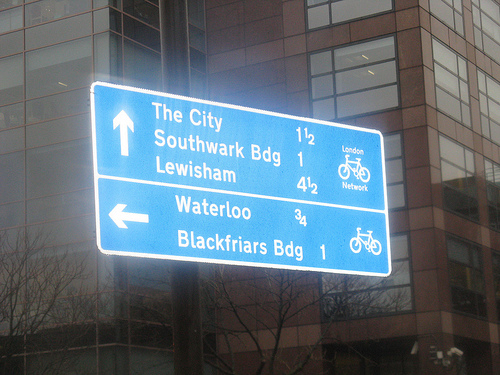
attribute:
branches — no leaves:
[182, 269, 387, 373]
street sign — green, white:
[87, 77, 394, 281]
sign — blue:
[87, 80, 395, 279]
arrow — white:
[108, 110, 134, 159]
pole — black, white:
[169, 280, 209, 372]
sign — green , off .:
[52, 62, 403, 295]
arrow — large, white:
[91, 198, 168, 231]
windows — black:
[440, 133, 487, 227]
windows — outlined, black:
[298, 26, 415, 109]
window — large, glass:
[307, 33, 397, 121]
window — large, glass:
[320, 235, 412, 320]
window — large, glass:
[380, 128, 406, 208]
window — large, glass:
[430, 35, 472, 128]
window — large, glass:
[445, 235, 487, 321]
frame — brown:
[285, 10, 425, 140]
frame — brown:
[282, 2, 417, 54]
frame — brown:
[348, 105, 432, 230]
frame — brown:
[294, 220, 441, 340]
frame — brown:
[431, 205, 498, 340]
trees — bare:
[205, 261, 396, 371]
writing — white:
[165, 190, 323, 267]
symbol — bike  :
[349, 223, 387, 256]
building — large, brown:
[3, 7, 496, 367]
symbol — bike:
[346, 223, 382, 256]